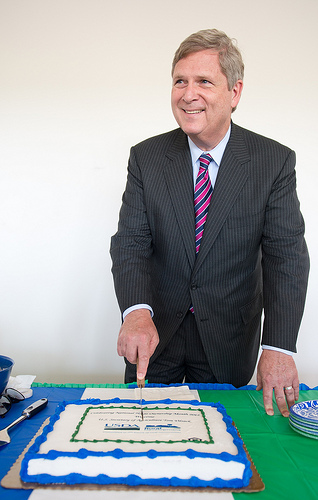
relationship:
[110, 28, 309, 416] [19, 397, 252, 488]
man cutting cake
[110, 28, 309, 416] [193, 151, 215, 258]
man wearing striped tie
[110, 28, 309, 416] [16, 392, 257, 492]
man cutting cake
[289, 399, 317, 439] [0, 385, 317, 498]
plates stacked on table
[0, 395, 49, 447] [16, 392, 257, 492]
spatula resting on cake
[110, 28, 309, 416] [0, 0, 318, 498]
man standing in room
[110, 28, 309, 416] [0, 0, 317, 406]
man standing in room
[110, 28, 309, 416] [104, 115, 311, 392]
man wearing suit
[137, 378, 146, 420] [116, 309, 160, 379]
knife in hand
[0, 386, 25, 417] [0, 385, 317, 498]
eyeglasses on table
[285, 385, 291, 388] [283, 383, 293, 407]
ring on finger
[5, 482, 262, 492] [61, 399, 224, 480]
cardboard under cake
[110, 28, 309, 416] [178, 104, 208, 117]
man has smile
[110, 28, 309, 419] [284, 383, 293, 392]
man wearing a ring